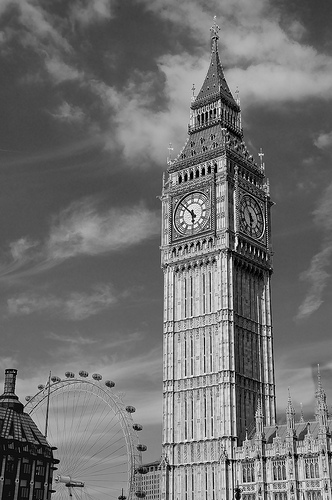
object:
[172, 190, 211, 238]
5:53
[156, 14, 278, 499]
tower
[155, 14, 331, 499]
building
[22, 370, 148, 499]
ferris wheel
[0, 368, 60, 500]
building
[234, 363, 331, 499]
building section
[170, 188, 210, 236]
clock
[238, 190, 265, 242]
clock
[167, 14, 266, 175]
roof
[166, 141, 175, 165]
decoration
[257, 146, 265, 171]
decoration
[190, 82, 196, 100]
decoration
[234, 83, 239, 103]
decoration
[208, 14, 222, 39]
decoration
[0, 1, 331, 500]
sky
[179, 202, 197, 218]
clock hand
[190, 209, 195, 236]
clock hand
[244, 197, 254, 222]
clock hand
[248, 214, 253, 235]
clock hand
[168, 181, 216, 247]
clock frame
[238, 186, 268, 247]
clock frame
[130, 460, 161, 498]
building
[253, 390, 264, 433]
steeple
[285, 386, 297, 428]
steeple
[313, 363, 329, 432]
steeple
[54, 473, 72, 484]
center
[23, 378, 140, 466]
empty area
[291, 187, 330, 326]
cloud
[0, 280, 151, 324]
cloud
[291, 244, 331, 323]
cloud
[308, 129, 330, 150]
cloud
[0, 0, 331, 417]
cloud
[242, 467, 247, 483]
window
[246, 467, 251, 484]
window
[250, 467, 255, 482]
window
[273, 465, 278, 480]
window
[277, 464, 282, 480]
window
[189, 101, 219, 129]
balcony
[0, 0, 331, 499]
cityscape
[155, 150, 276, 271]
section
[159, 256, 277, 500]
base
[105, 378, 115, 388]
car